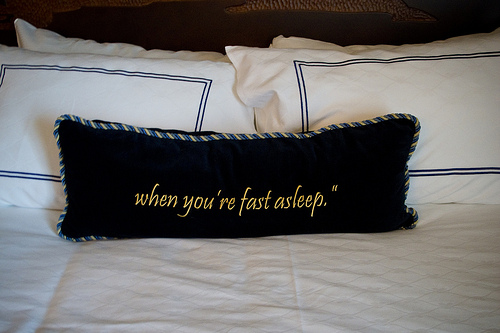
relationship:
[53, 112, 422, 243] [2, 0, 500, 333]
blue and gold trim on a bed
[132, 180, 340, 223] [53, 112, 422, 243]
gold words on a blue and gold trim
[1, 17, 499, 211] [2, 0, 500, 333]
pillows on a bed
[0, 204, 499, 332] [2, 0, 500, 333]
white sheets on a bed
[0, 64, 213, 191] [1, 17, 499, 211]
blue lines on a pillows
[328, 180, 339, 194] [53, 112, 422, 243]
quotation marks on a blue and gold trim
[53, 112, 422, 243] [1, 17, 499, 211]
blue and gold trim in front of pillows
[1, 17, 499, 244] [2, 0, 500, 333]
pillows on a bed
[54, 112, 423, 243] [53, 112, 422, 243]
blue and gold trim on a blue and gold trim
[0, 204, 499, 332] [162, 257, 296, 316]
white sheets that are wrinkled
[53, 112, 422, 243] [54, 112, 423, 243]
blue and gold trim with blue and gold trim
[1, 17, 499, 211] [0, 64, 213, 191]
pillows with blue lines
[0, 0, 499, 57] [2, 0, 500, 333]
brown headboard on bed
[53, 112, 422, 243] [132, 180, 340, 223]
blue and gold trim with gold words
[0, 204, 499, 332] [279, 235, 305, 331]
white sheets with designed lines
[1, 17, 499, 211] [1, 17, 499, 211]
pillows behind pillows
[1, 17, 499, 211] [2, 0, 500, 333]
pillows on bed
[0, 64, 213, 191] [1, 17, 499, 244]
blue lines on pillows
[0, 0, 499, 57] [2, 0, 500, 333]
brown headboard on a bed